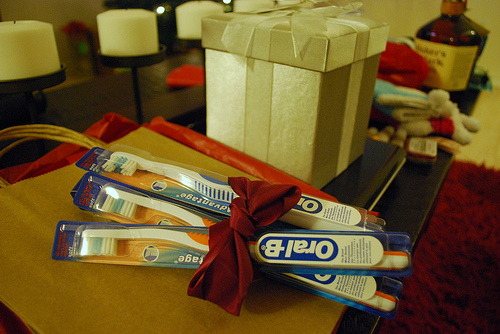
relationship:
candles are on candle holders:
[0, 2, 298, 91] [7, 44, 212, 147]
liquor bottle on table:
[404, 4, 495, 107] [11, 75, 496, 333]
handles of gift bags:
[0, 116, 111, 193] [3, 129, 365, 333]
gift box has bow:
[197, 6, 392, 192] [217, 3, 370, 67]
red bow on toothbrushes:
[178, 172, 307, 321] [49, 143, 415, 320]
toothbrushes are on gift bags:
[49, 143, 415, 320] [3, 129, 365, 333]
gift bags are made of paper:
[3, 129, 365, 333] [27, 186, 56, 228]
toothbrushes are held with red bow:
[49, 143, 415, 320] [178, 172, 307, 321]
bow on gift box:
[217, 3, 370, 67] [197, 6, 392, 192]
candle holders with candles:
[7, 44, 212, 147] [0, 2, 298, 91]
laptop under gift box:
[320, 131, 411, 213] [197, 6, 392, 192]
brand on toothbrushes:
[257, 230, 336, 270] [49, 143, 415, 320]